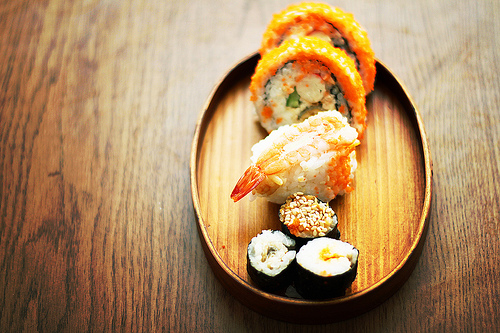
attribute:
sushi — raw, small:
[248, 230, 296, 295]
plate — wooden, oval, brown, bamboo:
[191, 50, 434, 326]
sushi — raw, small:
[298, 239, 360, 300]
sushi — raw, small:
[278, 196, 340, 242]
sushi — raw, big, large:
[230, 109, 360, 207]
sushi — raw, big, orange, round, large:
[251, 36, 367, 142]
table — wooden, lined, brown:
[1, 0, 500, 333]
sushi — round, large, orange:
[260, 3, 376, 94]